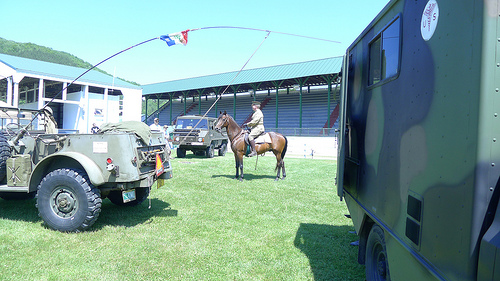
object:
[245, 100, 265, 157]
man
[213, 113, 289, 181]
horse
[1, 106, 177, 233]
jeep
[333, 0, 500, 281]
troop carrier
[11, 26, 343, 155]
antenna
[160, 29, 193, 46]
flag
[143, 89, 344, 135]
grandstand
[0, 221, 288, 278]
grass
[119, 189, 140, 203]
license plate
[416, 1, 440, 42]
symbol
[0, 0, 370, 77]
sky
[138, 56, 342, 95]
roof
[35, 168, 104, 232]
tire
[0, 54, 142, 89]
roof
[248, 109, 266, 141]
uniform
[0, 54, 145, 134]
building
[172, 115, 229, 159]
vehicle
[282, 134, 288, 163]
tail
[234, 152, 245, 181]
front leg